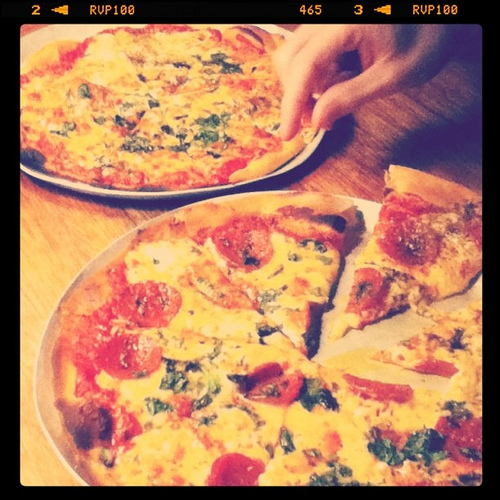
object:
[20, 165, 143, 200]
edge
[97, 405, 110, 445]
onion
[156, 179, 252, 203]
edge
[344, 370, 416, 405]
tomato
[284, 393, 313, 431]
pineapple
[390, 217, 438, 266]
pepperoni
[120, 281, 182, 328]
pepperoni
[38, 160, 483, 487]
pizza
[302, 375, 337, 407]
parsley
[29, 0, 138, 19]
text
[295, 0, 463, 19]
text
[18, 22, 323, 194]
pizza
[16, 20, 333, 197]
plate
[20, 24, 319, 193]
pizza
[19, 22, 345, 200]
dish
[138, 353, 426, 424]
garnishments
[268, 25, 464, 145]
hand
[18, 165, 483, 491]
crust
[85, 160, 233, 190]
sauce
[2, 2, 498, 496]
border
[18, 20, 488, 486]
picture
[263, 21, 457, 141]
person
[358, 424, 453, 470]
spinach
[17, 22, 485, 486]
table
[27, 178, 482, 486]
pizza plate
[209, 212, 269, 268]
pepperoni